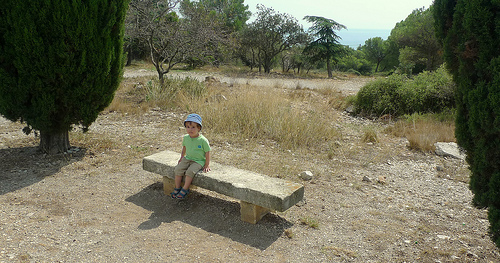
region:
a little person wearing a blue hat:
[179, 112, 208, 124]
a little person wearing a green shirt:
[178, 132, 206, 159]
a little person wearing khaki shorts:
[163, 158, 208, 177]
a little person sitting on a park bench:
[165, 108, 214, 203]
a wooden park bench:
[141, 142, 309, 227]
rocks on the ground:
[358, 157, 462, 224]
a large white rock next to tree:
[417, 138, 468, 165]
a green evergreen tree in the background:
[308, 9, 346, 77]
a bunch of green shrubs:
[336, 63, 456, 116]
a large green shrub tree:
[1, 0, 132, 175]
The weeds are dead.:
[209, 74, 387, 132]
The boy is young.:
[150, 108, 227, 208]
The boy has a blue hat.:
[158, 87, 216, 212]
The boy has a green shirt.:
[150, 87, 208, 209]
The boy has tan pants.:
[153, 102, 223, 209]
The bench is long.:
[141, 147, 307, 219]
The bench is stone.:
[135, 128, 302, 226]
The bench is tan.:
[140, 142, 302, 238]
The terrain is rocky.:
[323, 172, 468, 251]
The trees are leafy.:
[375, 22, 472, 133]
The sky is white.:
[318, 2, 391, 15]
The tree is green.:
[0, 0, 120, 158]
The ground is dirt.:
[23, 176, 133, 257]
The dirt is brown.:
[16, 176, 116, 251]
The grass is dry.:
[233, 87, 330, 153]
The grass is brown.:
[239, 98, 317, 146]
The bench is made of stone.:
[139, 137, 306, 229]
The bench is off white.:
[139, 145, 311, 225]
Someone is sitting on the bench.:
[147, 99, 234, 213]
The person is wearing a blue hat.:
[175, 106, 210, 141]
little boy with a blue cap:
[168, 109, 207, 201]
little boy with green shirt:
[176, 109, 216, 200]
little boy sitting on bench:
[138, 120, 315, 240]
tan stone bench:
[164, 139, 330, 218]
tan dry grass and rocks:
[236, 85, 448, 189]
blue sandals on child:
[163, 179, 193, 212]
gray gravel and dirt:
[353, 158, 477, 218]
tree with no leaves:
[133, 0, 230, 87]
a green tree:
[1, 4, 134, 182]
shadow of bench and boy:
[128, 172, 282, 258]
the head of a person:
[178, 108, 206, 136]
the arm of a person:
[198, 137, 213, 164]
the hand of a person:
[199, 162, 212, 174]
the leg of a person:
[181, 161, 202, 190]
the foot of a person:
[174, 185, 191, 198]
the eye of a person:
[187, 120, 197, 130]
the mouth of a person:
[184, 127, 195, 136]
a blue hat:
[178, 107, 208, 127]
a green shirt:
[176, 129, 214, 170]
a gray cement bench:
[140, 145, 307, 227]